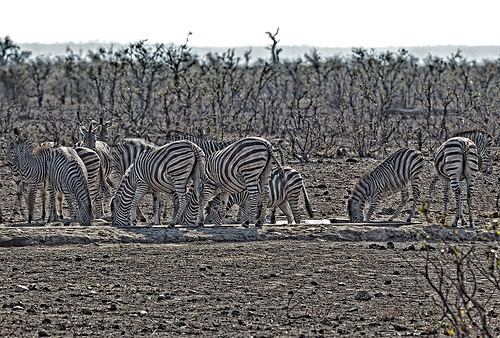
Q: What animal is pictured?
A: Zebra.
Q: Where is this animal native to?
A: Africa.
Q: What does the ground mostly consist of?
A: Dirt.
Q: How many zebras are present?
A: Ten.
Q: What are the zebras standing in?
A: Water.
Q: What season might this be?
A: Dry season.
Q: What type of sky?
A: Overcast.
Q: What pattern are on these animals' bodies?
A: Striped.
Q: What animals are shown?
A: Zebras.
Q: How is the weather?
A: Clear.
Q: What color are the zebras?
A: Black and white.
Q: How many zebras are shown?
A: Ten.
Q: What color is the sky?
A: White.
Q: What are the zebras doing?
A: Grazing.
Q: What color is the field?
A: Brown.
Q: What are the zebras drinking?
A: Water.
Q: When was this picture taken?
A: Afternoon.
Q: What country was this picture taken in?
A: Africa.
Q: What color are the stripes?
A: Black.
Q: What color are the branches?
A: Brown.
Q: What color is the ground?
A: Brown.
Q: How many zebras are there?
A: 12.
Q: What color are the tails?
A: Black.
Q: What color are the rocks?
A: Gray.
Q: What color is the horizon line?
A: Gray.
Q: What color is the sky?
A: White.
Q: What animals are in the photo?
A: Zebras.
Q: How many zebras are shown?
A: 11.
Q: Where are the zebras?
A: At watering hole.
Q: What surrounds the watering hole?
A: Stone.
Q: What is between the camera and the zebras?
A: Dirt.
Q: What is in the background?
A: Trees.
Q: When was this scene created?
A: Daytime.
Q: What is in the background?
A: Trees.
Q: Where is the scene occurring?
A: Wilderness.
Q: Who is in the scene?
A: No one.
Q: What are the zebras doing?
A: Drinking.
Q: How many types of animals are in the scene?
A: One.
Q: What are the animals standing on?
A: Dirt.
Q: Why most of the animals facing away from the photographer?
A: Because they are eating or drinking.